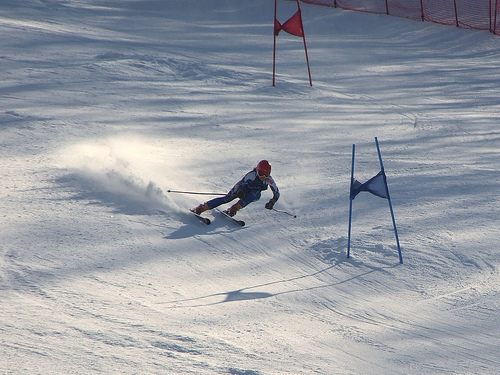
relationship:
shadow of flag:
[157, 256, 385, 310] [352, 169, 384, 201]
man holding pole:
[189, 159, 281, 223] [268, 206, 299, 221]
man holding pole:
[189, 159, 281, 223] [165, 186, 229, 200]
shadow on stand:
[157, 256, 385, 310] [344, 138, 406, 272]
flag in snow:
[268, 0, 317, 86] [1, 0, 498, 374]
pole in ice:
[372, 134, 404, 262] [1, 0, 498, 372]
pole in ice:
[346, 142, 356, 257] [1, 0, 498, 372]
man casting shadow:
[189, 159, 281, 223] [164, 210, 249, 239]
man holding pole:
[189, 156, 289, 223] [159, 184, 299, 224]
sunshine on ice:
[3, 255, 342, 373] [1, 0, 498, 372]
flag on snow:
[344, 165, 401, 210] [324, 225, 441, 311]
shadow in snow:
[157, 256, 385, 310] [1, 0, 498, 374]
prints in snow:
[246, 264, 485, 344] [1, 0, 498, 374]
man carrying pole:
[189, 159, 281, 223] [164, 183, 244, 203]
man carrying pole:
[189, 159, 281, 223] [265, 195, 303, 226]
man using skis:
[189, 159, 281, 223] [170, 201, 248, 226]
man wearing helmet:
[189, 159, 281, 223] [247, 150, 279, 182]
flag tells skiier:
[273, 3, 318, 91] [180, 162, 297, 235]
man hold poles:
[189, 159, 281, 223] [149, 164, 217, 201]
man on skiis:
[189, 159, 281, 223] [173, 195, 248, 239]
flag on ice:
[268, 0, 317, 86] [189, 4, 369, 126]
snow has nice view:
[1, 0, 498, 374] [13, 15, 242, 110]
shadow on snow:
[142, 233, 384, 343] [1, 0, 498, 374]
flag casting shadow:
[344, 135, 406, 266] [159, 261, 403, 308]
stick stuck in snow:
[374, 138, 402, 262] [1, 0, 498, 374]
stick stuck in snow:
[345, 144, 357, 257] [1, 0, 498, 374]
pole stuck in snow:
[346, 142, 356, 257] [1, 0, 498, 374]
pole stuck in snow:
[372, 134, 407, 266] [1, 0, 498, 374]